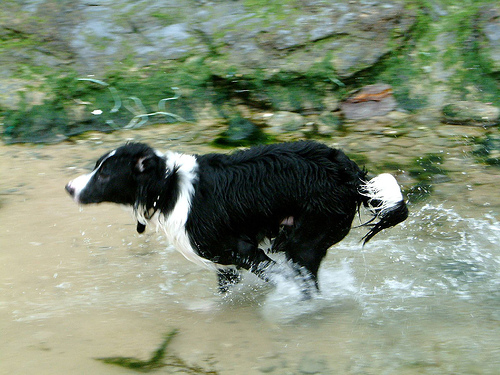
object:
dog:
[66, 139, 407, 309]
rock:
[340, 83, 396, 121]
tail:
[364, 169, 409, 247]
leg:
[285, 226, 350, 305]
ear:
[139, 156, 166, 175]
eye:
[99, 171, 112, 180]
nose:
[64, 183, 76, 196]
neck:
[139, 152, 178, 219]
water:
[1, 147, 499, 373]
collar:
[134, 162, 172, 235]